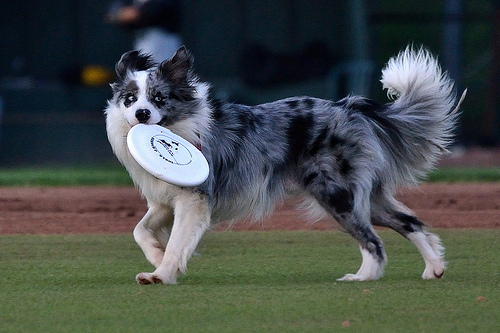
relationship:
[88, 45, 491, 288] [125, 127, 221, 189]
dog with frisbee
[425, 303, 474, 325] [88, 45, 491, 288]
grass under dog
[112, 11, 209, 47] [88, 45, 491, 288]
person behind dog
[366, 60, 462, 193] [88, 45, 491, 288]
tail of dog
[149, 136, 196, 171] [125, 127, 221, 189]
logo on frisbee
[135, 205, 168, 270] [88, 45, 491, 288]
leg of dog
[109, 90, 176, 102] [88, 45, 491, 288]
eyes of dog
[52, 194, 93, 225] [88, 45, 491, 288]
dirt behind dog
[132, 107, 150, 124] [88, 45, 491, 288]
nose of dog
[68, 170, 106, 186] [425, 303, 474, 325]
part of grass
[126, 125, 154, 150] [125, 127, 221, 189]
part of frisbee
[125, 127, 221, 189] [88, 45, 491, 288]
frisbee and dog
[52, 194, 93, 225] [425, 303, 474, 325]
dirt by grass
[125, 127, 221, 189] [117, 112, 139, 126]
frisbee in mouth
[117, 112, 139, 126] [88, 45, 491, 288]
mouth of dog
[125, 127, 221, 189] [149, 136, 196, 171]
frisbee has logo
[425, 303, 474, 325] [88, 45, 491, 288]
grass behind dog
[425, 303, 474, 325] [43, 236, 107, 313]
grass on field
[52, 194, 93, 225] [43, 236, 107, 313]
dirt on field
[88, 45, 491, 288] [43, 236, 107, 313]
dog on field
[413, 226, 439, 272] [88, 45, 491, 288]
paw of dog